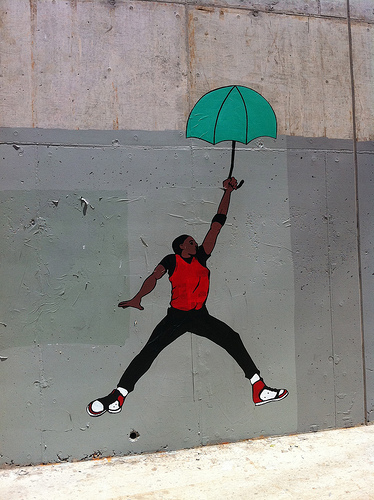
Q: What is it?
A: Painting.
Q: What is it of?
A: A man.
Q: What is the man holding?
A: Umbrella.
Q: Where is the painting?
A: On the wall.